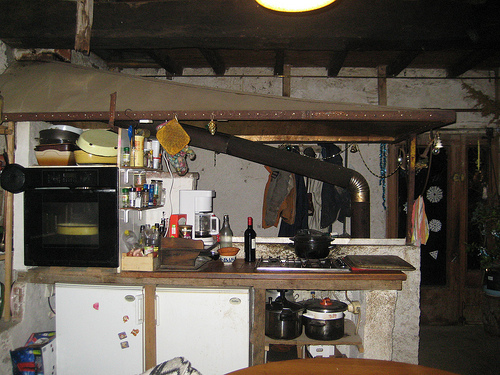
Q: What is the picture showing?
A: It is showing a kitchen.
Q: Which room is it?
A: It is a kitchen.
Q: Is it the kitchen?
A: Yes, it is the kitchen.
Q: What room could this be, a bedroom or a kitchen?
A: It is a kitchen.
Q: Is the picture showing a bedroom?
A: No, the picture is showing a kitchen.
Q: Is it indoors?
A: Yes, it is indoors.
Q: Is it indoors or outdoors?
A: It is indoors.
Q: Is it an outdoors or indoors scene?
A: It is indoors.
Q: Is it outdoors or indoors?
A: It is indoors.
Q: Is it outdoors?
A: No, it is indoors.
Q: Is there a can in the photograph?
A: No, there are no cans.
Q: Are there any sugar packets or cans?
A: No, there are no cans or sugar packets.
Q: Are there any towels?
A: Yes, there is a towel.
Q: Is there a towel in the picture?
A: Yes, there is a towel.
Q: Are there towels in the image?
A: Yes, there is a towel.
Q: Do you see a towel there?
A: Yes, there is a towel.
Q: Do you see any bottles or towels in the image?
A: Yes, there is a towel.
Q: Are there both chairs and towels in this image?
A: No, there is a towel but no chairs.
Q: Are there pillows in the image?
A: No, there are no pillows.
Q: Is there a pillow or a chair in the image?
A: No, there are no pillows or chairs.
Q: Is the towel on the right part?
A: Yes, the towel is on the right of the image.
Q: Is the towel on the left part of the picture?
A: No, the towel is on the right of the image.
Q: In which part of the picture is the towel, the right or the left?
A: The towel is on the right of the image.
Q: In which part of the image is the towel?
A: The towel is on the right of the image.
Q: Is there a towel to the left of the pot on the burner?
A: No, the towel is to the right of the pot.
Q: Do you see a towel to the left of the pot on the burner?
A: No, the towel is to the right of the pot.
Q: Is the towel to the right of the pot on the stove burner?
A: Yes, the towel is to the right of the pot.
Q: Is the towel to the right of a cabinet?
A: No, the towel is to the right of the pot.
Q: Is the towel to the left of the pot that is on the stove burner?
A: No, the towel is to the right of the pot.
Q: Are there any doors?
A: Yes, there is a door.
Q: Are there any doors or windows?
A: Yes, there is a door.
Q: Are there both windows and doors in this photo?
A: No, there is a door but no windows.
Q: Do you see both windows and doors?
A: No, there is a door but no windows.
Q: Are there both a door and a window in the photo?
A: No, there is a door but no windows.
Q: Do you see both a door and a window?
A: No, there is a door but no windows.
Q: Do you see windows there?
A: No, there are no windows.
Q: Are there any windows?
A: No, there are no windows.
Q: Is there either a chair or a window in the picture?
A: No, there are no windows or chairs.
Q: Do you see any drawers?
A: No, there are no drawers.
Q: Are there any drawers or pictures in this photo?
A: No, there are no drawers or pictures.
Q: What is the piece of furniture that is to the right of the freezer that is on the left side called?
A: The piece of furniture is a shelf.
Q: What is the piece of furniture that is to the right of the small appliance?
A: The piece of furniture is a shelf.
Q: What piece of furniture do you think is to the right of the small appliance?
A: The piece of furniture is a shelf.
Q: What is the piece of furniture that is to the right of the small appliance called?
A: The piece of furniture is a shelf.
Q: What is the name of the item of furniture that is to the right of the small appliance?
A: The piece of furniture is a shelf.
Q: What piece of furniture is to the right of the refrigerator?
A: The piece of furniture is a shelf.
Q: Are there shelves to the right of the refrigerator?
A: Yes, there is a shelf to the right of the refrigerator.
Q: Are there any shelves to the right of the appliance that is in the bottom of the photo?
A: Yes, there is a shelf to the right of the refrigerator.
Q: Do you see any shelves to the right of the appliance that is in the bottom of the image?
A: Yes, there is a shelf to the right of the refrigerator.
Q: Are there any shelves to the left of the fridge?
A: No, the shelf is to the right of the fridge.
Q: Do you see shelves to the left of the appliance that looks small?
A: No, the shelf is to the right of the fridge.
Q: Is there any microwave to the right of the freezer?
A: No, there is a shelf to the right of the freezer.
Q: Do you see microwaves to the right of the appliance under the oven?
A: No, there is a shelf to the right of the freezer.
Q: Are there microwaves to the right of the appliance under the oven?
A: No, there is a shelf to the right of the freezer.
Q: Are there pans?
A: Yes, there is a pan.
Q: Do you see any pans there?
A: Yes, there is a pan.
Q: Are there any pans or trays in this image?
A: Yes, there is a pan.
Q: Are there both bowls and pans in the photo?
A: Yes, there are both a pan and a bowl.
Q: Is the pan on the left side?
A: Yes, the pan is on the left of the image.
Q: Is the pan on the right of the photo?
A: No, the pan is on the left of the image.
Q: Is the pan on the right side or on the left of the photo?
A: The pan is on the left of the image.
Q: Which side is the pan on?
A: The pan is on the left of the image.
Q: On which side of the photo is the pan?
A: The pan is on the left of the image.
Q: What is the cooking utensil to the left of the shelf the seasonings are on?
A: The cooking utensil is a pan.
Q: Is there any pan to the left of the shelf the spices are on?
A: Yes, there is a pan to the left of the shelf.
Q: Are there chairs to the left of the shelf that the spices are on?
A: No, there is a pan to the left of the shelf.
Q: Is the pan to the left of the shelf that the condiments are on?
A: Yes, the pan is to the left of the shelf.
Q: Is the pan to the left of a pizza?
A: No, the pan is to the left of the shelf.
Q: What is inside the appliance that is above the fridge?
A: The pan is inside the oven.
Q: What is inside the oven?
A: The pan is inside the oven.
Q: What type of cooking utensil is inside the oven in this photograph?
A: The cooking utensil is a pan.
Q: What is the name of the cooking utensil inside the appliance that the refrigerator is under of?
A: The cooking utensil is a pan.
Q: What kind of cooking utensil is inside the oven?
A: The cooking utensil is a pan.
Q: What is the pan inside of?
A: The pan is inside the oven.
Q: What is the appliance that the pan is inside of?
A: The appliance is an oven.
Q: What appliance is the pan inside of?
A: The pan is inside the oven.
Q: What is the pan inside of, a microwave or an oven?
A: The pan is inside an oven.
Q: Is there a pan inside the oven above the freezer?
A: Yes, there is a pan inside the oven.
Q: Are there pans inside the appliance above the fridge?
A: Yes, there is a pan inside the oven.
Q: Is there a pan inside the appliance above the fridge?
A: Yes, there is a pan inside the oven.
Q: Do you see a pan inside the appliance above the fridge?
A: Yes, there is a pan inside the oven.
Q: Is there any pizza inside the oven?
A: No, there is a pan inside the oven.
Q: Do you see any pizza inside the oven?
A: No, there is a pan inside the oven.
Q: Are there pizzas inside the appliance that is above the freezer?
A: No, there is a pan inside the oven.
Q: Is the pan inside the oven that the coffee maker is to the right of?
A: Yes, the pan is inside the oven.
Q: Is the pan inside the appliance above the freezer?
A: Yes, the pan is inside the oven.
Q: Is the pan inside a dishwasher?
A: No, the pan is inside the oven.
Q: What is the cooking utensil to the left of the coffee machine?
A: The cooking utensil is a pan.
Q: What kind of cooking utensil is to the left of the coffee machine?
A: The cooking utensil is a pan.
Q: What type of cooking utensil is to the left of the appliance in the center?
A: The cooking utensil is a pan.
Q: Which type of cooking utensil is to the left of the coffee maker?
A: The cooking utensil is a pan.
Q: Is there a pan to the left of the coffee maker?
A: Yes, there is a pan to the left of the coffee maker.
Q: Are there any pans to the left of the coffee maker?
A: Yes, there is a pan to the left of the coffee maker.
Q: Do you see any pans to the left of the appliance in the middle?
A: Yes, there is a pan to the left of the coffee maker.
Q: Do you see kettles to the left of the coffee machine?
A: No, there is a pan to the left of the coffee machine.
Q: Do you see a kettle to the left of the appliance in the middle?
A: No, there is a pan to the left of the coffee machine.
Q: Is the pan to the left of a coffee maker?
A: Yes, the pan is to the left of a coffee maker.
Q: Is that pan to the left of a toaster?
A: No, the pan is to the left of a coffee maker.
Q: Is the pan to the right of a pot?
A: No, the pan is to the left of a pot.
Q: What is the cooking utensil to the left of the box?
A: The cooking utensil is a pan.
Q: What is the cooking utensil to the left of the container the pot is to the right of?
A: The cooking utensil is a pan.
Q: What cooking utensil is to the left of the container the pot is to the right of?
A: The cooking utensil is a pan.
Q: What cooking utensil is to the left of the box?
A: The cooking utensil is a pan.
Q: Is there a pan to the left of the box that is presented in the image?
A: Yes, there is a pan to the left of the box.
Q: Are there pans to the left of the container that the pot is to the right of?
A: Yes, there is a pan to the left of the box.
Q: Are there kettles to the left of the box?
A: No, there is a pan to the left of the box.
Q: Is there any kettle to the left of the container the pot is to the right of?
A: No, there is a pan to the left of the box.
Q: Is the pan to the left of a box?
A: Yes, the pan is to the left of a box.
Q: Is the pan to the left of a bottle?
A: No, the pan is to the left of a box.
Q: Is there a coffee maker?
A: Yes, there is a coffee maker.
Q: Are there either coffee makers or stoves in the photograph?
A: Yes, there is a coffee maker.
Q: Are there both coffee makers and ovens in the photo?
A: Yes, there are both a coffee maker and an oven.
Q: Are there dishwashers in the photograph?
A: No, there are no dishwashers.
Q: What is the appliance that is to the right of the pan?
A: The appliance is a coffee maker.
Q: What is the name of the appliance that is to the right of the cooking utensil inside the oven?
A: The appliance is a coffee maker.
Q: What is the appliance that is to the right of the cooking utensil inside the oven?
A: The appliance is a coffee maker.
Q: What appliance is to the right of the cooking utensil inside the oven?
A: The appliance is a coffee maker.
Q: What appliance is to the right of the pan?
A: The appliance is a coffee maker.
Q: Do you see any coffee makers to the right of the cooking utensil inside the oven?
A: Yes, there is a coffee maker to the right of the pan.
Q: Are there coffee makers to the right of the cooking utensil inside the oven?
A: Yes, there is a coffee maker to the right of the pan.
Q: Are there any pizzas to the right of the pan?
A: No, there is a coffee maker to the right of the pan.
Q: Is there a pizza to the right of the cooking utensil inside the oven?
A: No, there is a coffee maker to the right of the pan.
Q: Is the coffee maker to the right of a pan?
A: Yes, the coffee maker is to the right of a pan.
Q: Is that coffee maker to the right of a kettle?
A: No, the coffee maker is to the right of a pan.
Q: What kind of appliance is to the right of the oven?
A: The appliance is a coffee maker.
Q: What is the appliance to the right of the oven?
A: The appliance is a coffee maker.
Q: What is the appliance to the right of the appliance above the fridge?
A: The appliance is a coffee maker.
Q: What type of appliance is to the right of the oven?
A: The appliance is a coffee maker.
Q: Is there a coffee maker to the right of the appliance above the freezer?
A: Yes, there is a coffee maker to the right of the oven.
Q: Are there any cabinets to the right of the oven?
A: No, there is a coffee maker to the right of the oven.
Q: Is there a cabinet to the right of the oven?
A: No, there is a coffee maker to the right of the oven.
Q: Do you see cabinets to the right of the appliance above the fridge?
A: No, there is a coffee maker to the right of the oven.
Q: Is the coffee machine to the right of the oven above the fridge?
A: Yes, the coffee machine is to the right of the oven.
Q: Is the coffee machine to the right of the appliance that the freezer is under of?
A: Yes, the coffee machine is to the right of the oven.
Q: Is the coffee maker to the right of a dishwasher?
A: No, the coffee maker is to the right of the oven.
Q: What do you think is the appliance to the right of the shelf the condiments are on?
A: The appliance is a coffee maker.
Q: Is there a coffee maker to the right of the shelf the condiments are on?
A: Yes, there is a coffee maker to the right of the shelf.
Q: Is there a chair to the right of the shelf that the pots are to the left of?
A: No, there is a coffee maker to the right of the shelf.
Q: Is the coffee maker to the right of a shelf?
A: Yes, the coffee maker is to the right of a shelf.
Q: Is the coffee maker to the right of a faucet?
A: No, the coffee maker is to the right of a shelf.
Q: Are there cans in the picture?
A: No, there are no cans.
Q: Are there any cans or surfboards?
A: No, there are no cans or surfboards.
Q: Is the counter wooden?
A: Yes, the counter is wooden.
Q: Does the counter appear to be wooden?
A: Yes, the counter is wooden.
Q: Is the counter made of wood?
A: Yes, the counter is made of wood.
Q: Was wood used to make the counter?
A: Yes, the counter is made of wood.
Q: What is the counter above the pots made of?
A: The counter is made of wood.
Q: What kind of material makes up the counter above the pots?
A: The counter is made of wood.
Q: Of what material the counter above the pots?
A: The counter is made of wood.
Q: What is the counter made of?
A: The counter is made of wood.